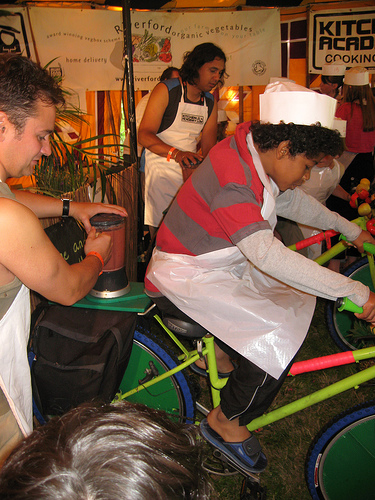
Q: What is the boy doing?
A: Riding.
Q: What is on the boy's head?
A: Hat.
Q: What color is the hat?
A: White.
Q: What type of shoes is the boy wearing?
A: Sandals.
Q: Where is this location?
A: Restaurant.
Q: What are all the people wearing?
A: Apron.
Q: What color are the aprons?
A: White.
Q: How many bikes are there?
A: Two.